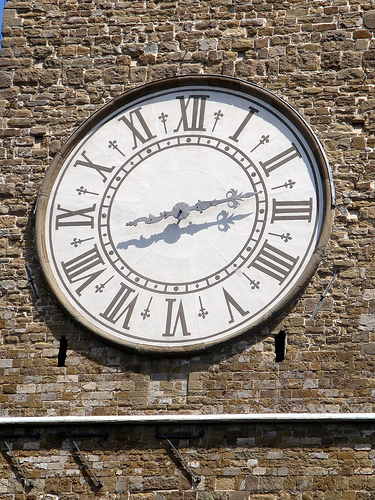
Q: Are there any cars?
A: No, there are no cars.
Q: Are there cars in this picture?
A: No, there are no cars.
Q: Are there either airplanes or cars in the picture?
A: No, there are no cars or airplanes.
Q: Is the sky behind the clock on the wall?
A: Yes, the sky is behind the clock.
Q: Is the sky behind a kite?
A: No, the sky is behind the clock.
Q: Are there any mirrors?
A: No, there are no mirrors.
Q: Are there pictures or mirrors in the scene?
A: No, there are no mirrors or pictures.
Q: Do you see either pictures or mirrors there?
A: No, there are no mirrors or pictures.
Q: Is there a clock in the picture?
A: Yes, there is a clock.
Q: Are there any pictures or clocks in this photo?
A: Yes, there is a clock.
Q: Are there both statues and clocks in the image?
A: No, there is a clock but no statues.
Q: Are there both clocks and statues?
A: No, there is a clock but no statues.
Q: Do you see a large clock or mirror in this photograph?
A: Yes, there is a large clock.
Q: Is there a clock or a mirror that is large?
A: Yes, the clock is large.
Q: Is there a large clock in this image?
A: Yes, there is a large clock.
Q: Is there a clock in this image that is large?
A: Yes, there is a clock that is large.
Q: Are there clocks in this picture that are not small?
A: Yes, there is a large clock.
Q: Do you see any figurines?
A: No, there are no figurines.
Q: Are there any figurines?
A: No, there are no figurines.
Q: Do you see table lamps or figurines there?
A: No, there are no figurines or table lamps.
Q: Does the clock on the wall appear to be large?
A: Yes, the clock is large.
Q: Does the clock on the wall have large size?
A: Yes, the clock is large.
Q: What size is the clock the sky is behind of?
A: The clock is large.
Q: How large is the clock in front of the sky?
A: The clock is large.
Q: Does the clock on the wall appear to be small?
A: No, the clock is large.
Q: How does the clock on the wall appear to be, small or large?
A: The clock is large.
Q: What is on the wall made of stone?
A: The clock is on the wall.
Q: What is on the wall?
A: The clock is on the wall.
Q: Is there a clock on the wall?
A: Yes, there is a clock on the wall.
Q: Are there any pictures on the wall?
A: No, there is a clock on the wall.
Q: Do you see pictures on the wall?
A: No, there is a clock on the wall.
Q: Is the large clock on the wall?
A: Yes, the clock is on the wall.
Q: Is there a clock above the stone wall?
A: Yes, there is a clock above the wall.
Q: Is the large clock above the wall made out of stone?
A: Yes, the clock is above the wall.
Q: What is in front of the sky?
A: The clock is in front of the sky.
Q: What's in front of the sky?
A: The clock is in front of the sky.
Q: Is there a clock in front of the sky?
A: Yes, there is a clock in front of the sky.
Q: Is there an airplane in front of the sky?
A: No, there is a clock in front of the sky.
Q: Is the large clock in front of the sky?
A: Yes, the clock is in front of the sky.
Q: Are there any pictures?
A: No, there are no pictures.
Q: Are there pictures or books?
A: No, there are no pictures or books.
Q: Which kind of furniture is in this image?
A: The furniture is a shelf.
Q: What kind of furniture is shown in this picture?
A: The furniture is a shelf.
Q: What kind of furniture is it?
A: The piece of furniture is a shelf.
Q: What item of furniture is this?
A: This is a shelf.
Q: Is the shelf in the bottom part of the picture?
A: Yes, the shelf is in the bottom of the image.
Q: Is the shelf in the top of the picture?
A: No, the shelf is in the bottom of the image.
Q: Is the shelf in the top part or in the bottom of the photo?
A: The shelf is in the bottom of the image.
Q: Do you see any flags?
A: No, there are no flags.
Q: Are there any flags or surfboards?
A: No, there are no flags or surfboards.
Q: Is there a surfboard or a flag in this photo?
A: No, there are no flags or surfboards.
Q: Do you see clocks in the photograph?
A: Yes, there is a clock.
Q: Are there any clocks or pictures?
A: Yes, there is a clock.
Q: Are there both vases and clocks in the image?
A: No, there is a clock but no vases.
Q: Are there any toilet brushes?
A: No, there are no toilet brushes.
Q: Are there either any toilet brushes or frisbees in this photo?
A: No, there are no toilet brushes or frisbees.